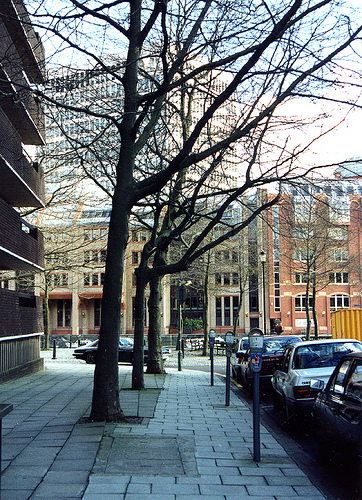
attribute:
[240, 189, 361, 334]
building — brown, brick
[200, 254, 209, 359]
tree — tall, skinny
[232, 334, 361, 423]
cars — four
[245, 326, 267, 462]
meter — parking, metal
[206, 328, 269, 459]
meters — parking, metal, three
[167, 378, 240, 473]
sidewalk — white, brick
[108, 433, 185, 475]
panels — access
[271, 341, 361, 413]
car — white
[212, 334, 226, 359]
table — picnic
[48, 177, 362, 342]
building — series, apartment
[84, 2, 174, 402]
tree — leaves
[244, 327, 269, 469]
meter — parking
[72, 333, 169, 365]
car — black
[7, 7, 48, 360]
space — five, parking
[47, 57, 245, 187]
building — tall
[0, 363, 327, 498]
sidewalk — brick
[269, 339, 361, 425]
car — white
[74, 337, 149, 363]
car — black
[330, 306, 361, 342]
container — yellow, metal